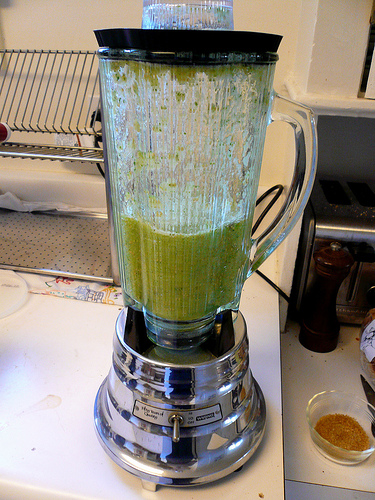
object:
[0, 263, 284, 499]
counter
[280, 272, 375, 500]
table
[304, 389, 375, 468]
dish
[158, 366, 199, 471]
reflections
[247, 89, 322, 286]
handle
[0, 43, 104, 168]
grate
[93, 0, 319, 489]
blender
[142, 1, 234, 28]
coveredopening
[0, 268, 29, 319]
lid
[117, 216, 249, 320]
green stuff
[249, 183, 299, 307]
cord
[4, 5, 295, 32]
wall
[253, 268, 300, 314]
cord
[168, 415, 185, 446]
button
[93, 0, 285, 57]
lid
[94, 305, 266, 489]
base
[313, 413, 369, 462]
stuff